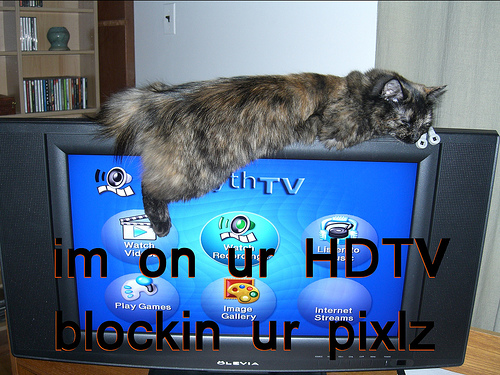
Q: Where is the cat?
A: On TV.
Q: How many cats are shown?
A: One.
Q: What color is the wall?
A: White.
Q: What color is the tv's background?
A: Blue.